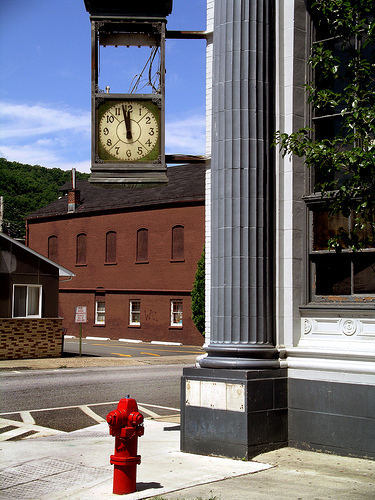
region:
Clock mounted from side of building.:
[67, 88, 190, 190]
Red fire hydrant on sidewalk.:
[97, 390, 167, 498]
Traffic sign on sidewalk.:
[62, 302, 109, 357]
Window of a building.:
[293, 188, 373, 307]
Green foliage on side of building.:
[307, 1, 373, 261]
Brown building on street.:
[18, 181, 213, 353]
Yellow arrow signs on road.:
[108, 347, 167, 364]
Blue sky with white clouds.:
[4, 6, 87, 150]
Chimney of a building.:
[63, 161, 82, 216]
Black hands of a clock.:
[120, 106, 137, 146]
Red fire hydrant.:
[88, 390, 164, 499]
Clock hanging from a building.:
[72, 12, 177, 181]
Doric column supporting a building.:
[207, 35, 291, 358]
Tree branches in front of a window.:
[277, 7, 373, 250]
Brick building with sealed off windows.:
[25, 225, 190, 272]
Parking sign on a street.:
[72, 296, 99, 362]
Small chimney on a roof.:
[53, 161, 90, 219]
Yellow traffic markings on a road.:
[95, 340, 176, 364]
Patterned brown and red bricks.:
[0, 318, 73, 355]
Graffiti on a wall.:
[127, 293, 169, 332]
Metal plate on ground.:
[32, 444, 91, 498]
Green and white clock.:
[57, 77, 174, 195]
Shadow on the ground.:
[136, 476, 171, 498]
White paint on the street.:
[0, 379, 108, 466]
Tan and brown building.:
[0, 311, 67, 354]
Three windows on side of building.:
[79, 285, 182, 347]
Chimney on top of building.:
[51, 184, 89, 212]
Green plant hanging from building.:
[305, 153, 370, 253]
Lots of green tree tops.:
[0, 145, 70, 217]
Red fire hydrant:
[97, 390, 151, 498]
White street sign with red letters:
[69, 302, 95, 323]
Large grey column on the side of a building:
[192, 0, 293, 377]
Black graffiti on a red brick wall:
[142, 306, 163, 324]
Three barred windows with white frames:
[87, 292, 188, 330]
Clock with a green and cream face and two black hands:
[84, 78, 172, 184]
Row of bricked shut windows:
[37, 223, 192, 268]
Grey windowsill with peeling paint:
[295, 274, 372, 315]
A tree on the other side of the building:
[189, 238, 219, 351]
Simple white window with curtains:
[10, 279, 51, 321]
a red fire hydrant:
[98, 400, 174, 496]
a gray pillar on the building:
[200, 211, 284, 353]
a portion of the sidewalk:
[287, 453, 367, 496]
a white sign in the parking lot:
[53, 295, 99, 362]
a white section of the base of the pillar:
[197, 381, 266, 435]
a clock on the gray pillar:
[87, 90, 173, 205]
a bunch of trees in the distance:
[4, 137, 88, 236]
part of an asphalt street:
[34, 383, 133, 403]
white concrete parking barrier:
[150, 334, 189, 358]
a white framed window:
[10, 281, 50, 332]